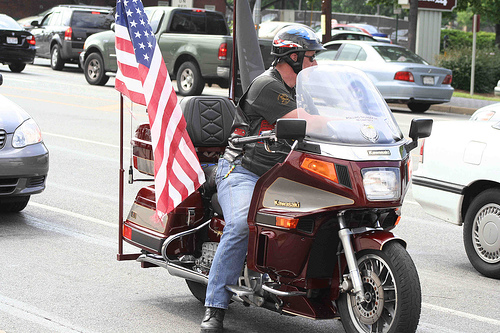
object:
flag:
[112, 1, 207, 227]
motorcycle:
[112, 62, 435, 333]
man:
[195, 22, 344, 330]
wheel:
[334, 235, 423, 332]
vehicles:
[253, 18, 393, 56]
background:
[0, 0, 498, 47]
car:
[0, 74, 50, 214]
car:
[409, 102, 500, 282]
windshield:
[292, 62, 404, 146]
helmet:
[267, 23, 327, 76]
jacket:
[227, 69, 318, 176]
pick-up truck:
[77, 5, 277, 97]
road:
[0, 59, 499, 331]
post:
[319, 0, 334, 47]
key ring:
[211, 157, 236, 181]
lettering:
[274, 200, 301, 208]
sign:
[169, 0, 197, 12]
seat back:
[175, 95, 245, 148]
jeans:
[203, 154, 265, 313]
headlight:
[360, 166, 402, 202]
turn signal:
[299, 153, 353, 192]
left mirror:
[404, 118, 433, 154]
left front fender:
[248, 199, 365, 322]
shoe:
[200, 304, 229, 333]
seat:
[198, 161, 235, 217]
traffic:
[0, 0, 498, 330]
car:
[314, 39, 455, 114]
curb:
[388, 101, 484, 117]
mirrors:
[274, 117, 307, 151]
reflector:
[122, 224, 132, 240]